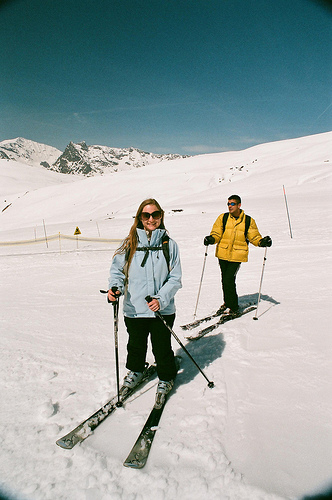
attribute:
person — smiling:
[107, 196, 184, 391]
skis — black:
[53, 357, 185, 471]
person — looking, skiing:
[201, 192, 273, 315]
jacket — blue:
[106, 227, 184, 320]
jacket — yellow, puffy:
[210, 210, 264, 265]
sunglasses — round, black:
[137, 210, 166, 222]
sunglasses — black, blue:
[226, 200, 241, 207]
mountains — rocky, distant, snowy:
[1, 135, 188, 178]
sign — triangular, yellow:
[73, 225, 82, 239]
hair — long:
[117, 199, 165, 288]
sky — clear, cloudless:
[3, 2, 331, 156]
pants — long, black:
[215, 258, 242, 314]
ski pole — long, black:
[143, 295, 217, 388]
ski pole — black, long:
[99, 284, 128, 407]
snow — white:
[1, 131, 332, 500]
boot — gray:
[119, 364, 147, 390]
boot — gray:
[154, 373, 177, 396]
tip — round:
[207, 382, 217, 389]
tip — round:
[115, 399, 126, 410]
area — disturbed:
[1, 338, 280, 500]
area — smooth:
[1, 136, 332, 291]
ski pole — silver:
[250, 241, 273, 324]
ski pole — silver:
[189, 242, 212, 324]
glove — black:
[202, 234, 216, 248]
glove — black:
[259, 235, 277, 250]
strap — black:
[220, 212, 230, 236]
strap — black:
[243, 215, 253, 244]